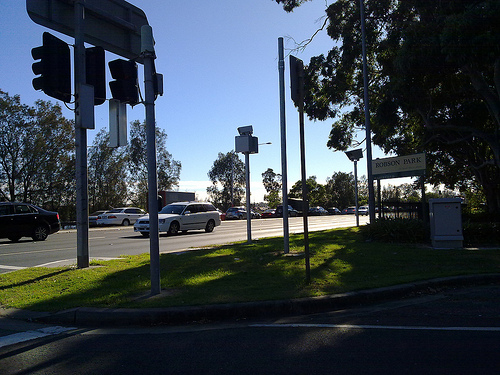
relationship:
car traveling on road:
[135, 199, 223, 240] [25, 173, 254, 265]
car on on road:
[4, 180, 69, 270] [8, 177, 159, 282]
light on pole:
[28, 31, 71, 107] [68, 2, 93, 271]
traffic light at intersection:
[29, 32, 70, 103] [0, 260, 75, 357]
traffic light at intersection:
[108, 56, 138, 106] [0, 260, 75, 357]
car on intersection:
[0, 202, 60, 242] [1, 239, 36, 311]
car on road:
[134, 200, 221, 237] [203, 220, 268, 239]